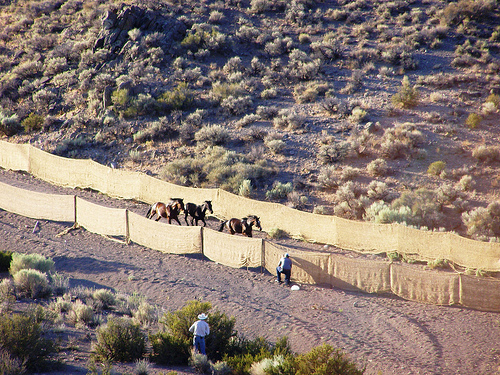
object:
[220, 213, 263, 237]
horse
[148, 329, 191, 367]
bush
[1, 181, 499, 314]
border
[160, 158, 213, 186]
bush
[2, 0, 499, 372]
ground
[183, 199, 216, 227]
horse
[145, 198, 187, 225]
horse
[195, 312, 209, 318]
hat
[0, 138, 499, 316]
chute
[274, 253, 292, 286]
man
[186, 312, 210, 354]
man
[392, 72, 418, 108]
trees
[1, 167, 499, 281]
road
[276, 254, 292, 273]
t-shirt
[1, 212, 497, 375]
dirt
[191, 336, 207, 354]
jeans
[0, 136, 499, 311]
enclosure